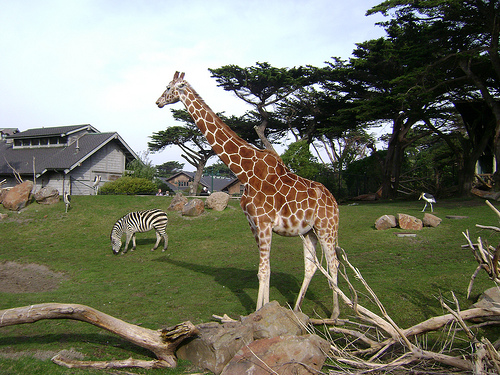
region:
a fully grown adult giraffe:
[140, 72, 350, 320]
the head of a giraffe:
[147, 71, 195, 122]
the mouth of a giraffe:
[155, 95, 163, 113]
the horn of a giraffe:
[164, 66, 191, 74]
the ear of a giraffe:
[168, 79, 193, 89]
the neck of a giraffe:
[184, 93, 246, 173]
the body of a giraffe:
[241, 149, 355, 240]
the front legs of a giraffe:
[237, 195, 282, 307]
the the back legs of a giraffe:
[290, 213, 338, 314]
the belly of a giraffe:
[264, 185, 322, 242]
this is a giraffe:
[154, 66, 331, 298]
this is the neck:
[185, 100, 241, 163]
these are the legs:
[247, 231, 342, 302]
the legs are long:
[239, 231, 354, 298]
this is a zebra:
[105, 202, 173, 260]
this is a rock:
[198, 300, 318, 371]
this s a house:
[50, 116, 121, 195]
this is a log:
[0, 291, 172, 371]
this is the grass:
[146, 249, 218, 306]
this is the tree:
[327, 28, 436, 120]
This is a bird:
[407, 185, 444, 218]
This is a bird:
[411, 184, 440, 218]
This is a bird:
[415, 186, 437, 221]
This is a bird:
[416, 186, 440, 216]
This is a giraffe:
[153, 62, 355, 364]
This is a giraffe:
[158, 56, 360, 333]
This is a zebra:
[103, 205, 182, 261]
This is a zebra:
[107, 202, 192, 275]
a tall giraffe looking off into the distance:
[151, 67, 341, 325]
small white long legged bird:
[416, 189, 438, 213]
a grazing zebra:
[109, 204, 171, 257]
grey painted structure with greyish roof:
[0, 126, 144, 197]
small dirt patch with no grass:
[1, 262, 61, 290]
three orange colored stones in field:
[372, 213, 442, 234]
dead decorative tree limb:
[0, 303, 194, 368]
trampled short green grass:
[77, 269, 192, 309]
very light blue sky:
[15, 25, 144, 115]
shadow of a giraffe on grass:
[151, 252, 329, 313]